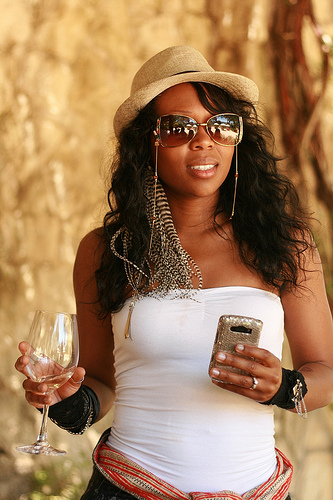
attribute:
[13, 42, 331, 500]
woman — attractive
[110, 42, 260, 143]
hat — straw, brown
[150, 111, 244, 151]
sunglasses — large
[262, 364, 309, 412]
wristband — black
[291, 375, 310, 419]
detail — metal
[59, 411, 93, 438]
detail — metal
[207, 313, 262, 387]
cell phone — grey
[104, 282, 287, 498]
tube top — white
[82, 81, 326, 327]
hair — long, wavy, black